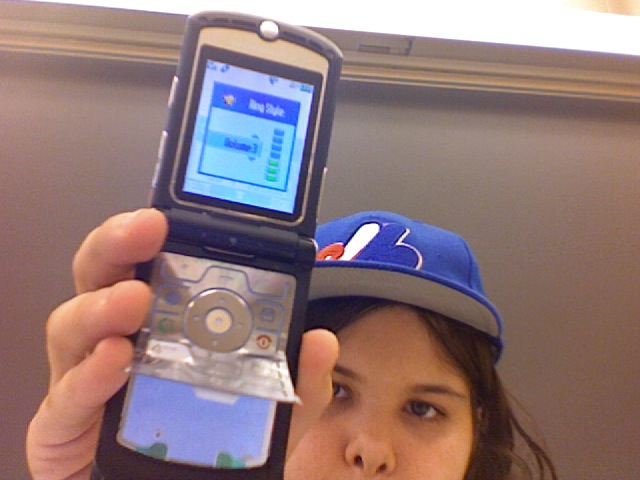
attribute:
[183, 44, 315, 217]
screen — on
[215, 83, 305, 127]
banner — blue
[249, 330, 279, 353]
button — red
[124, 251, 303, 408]
keyboard — broken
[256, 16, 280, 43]
carrier emblem — small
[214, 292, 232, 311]
arrow — small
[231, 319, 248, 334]
arrow — small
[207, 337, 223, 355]
arrow — small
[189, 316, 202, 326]
arrow — small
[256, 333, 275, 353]
button — red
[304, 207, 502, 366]
hat — blue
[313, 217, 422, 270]
logo — blue, red, white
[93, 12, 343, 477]
flip phone — broken, blue, white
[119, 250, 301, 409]
number pad — peeling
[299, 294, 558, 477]
hair — brown, stringy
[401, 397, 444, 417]
eye — blue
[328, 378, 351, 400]
eye — blue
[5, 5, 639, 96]
molding — white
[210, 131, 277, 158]
volume — 3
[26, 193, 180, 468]
fingers — three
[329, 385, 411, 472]
bridge — smooth